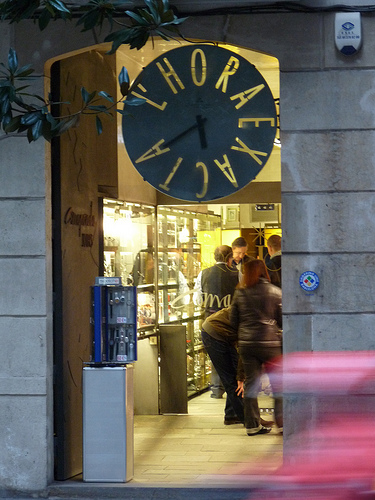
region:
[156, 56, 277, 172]
word on the clock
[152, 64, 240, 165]
gold and black clock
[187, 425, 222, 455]
brown ground below the people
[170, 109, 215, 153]
hands of the clock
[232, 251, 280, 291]
hair on the lady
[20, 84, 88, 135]
leaves next to the clock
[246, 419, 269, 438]
shoe on the person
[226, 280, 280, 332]
jacket on the girl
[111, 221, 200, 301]
glass next to the people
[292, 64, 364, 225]
lines on the building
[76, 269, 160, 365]
Display of watches on stand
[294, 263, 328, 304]
Sign on side of building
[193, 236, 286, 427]
Group of people inside store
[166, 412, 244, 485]
The floor is wood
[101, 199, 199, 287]
Display cases with items for sale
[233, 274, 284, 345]
Woman wearing a leather jacket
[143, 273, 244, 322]
Writing on the glass window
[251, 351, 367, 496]
Flash of light outside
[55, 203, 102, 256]
Sign on side of building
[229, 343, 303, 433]
Woman is wearing pants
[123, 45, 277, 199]
a clock on a building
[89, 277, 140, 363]
a display in a store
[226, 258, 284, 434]
a woman in a store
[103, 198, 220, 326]
a glass display case in a store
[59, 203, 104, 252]
a sign with the name of a store on it's door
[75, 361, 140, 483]
a metal stand holding a display case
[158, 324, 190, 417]
an open cabinet door on a display case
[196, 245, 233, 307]
a man in a store talking to another man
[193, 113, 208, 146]
the hour hand on a clock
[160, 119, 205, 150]
the minute hand on a clock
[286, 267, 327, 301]
symbol on the wall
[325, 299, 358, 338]
line on the wall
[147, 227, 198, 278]
glass next to the people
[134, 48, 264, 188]
gold and black clock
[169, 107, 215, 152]
hands on the clock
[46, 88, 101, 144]
leaves on the tree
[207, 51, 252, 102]
the letter R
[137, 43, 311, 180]
store sign is round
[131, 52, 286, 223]
letters on the sign are yellow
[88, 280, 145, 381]
watches in a case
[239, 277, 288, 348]
woman wearing a leather jacket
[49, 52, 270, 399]
entry into the store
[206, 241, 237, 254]
man is balding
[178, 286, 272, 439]
person bent over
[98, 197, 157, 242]
lights on in the showcases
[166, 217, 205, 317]
glass doors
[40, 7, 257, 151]
branches next to the store sign